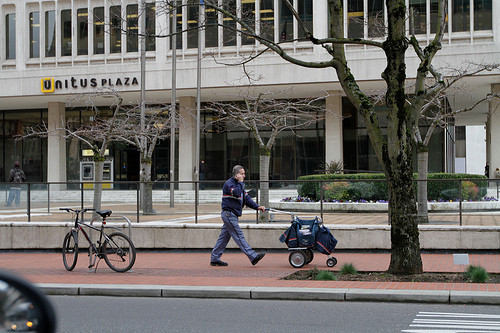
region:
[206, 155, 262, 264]
this is a man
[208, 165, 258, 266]
the man is walking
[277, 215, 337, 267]
this is a carrier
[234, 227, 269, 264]
the leg is in front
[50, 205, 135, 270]
this is a bike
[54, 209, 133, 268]
the bike is parked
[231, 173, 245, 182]
the man is speaking through the phone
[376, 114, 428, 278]
this is a tree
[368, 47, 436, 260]
the tree is tall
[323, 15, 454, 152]
the tree is branchy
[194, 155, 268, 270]
THE MAN IS WALKING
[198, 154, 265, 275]
THE MAN IS A MAIL MAN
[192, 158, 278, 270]
THE MAN IS TALKING ON THE PHONE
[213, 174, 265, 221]
THE MAN IS WEARING A JACKET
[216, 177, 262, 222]
THE MAN'S JACKET IS BLUE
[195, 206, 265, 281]
THE MAN IS WEARING GREY PANTS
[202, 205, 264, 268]
THE MAN'S PANTS HAVE A DARK STRIPE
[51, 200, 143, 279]
THIS IS A BIKE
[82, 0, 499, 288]
THIS IS A TREE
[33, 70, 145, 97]
THE BUILDING HAS A SIGN THAT READS UNITUS PLAZA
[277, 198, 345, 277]
a blue mail stroller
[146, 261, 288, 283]
red bricks of the sidewalk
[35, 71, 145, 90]
black lettering on the side of the building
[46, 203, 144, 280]
a black bicycle chained to a metal post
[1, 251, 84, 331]
the rearview mirror of a car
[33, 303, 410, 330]
black asphalt of the road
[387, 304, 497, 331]
white lettering on the road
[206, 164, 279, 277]
a mailman talking on his phone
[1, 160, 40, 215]
a man with a backpack in the courtyard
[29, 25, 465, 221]
several leafless trees in the courtyard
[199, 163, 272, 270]
man walking down the sidewalk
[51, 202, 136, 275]
bike parked on the sidewalk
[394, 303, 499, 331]
white paint on the ground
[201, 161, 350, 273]
man pushing a cart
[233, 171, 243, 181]
hand lifted to the face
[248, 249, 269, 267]
foot lifted off the ground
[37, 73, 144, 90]
black writing on the building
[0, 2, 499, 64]
row of thin windows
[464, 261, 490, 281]
small green plant frowing in the dirt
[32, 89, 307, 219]
three trees with no leaves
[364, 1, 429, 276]
a moss covered tree tunk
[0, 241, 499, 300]
a red brick sidewalk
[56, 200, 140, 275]
bike chained to a pole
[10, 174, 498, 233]
a metal and glass fence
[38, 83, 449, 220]
a few leafless trees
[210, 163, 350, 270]
a mailman pushing a stroller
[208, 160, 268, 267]
a man talking on the phone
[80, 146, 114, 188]
a pair of atm machines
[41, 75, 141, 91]
a store sign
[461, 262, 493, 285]
a few short plants